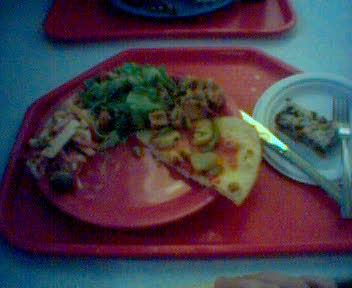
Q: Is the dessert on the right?
A: Yes, the dessert is on the right of the image.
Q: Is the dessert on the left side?
A: No, the dessert is on the right of the image.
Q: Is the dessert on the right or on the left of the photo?
A: The dessert is on the right of the image.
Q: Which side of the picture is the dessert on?
A: The dessert is on the right of the image.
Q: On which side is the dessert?
A: The dessert is on the right of the image.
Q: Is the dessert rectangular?
A: Yes, the dessert is rectangular.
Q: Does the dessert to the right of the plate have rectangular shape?
A: Yes, the dessert is rectangular.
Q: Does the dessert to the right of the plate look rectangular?
A: Yes, the dessert is rectangular.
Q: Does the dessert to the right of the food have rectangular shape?
A: Yes, the dessert is rectangular.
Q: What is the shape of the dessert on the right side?
A: The dessert is rectangular.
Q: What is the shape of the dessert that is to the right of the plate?
A: The dessert is rectangular.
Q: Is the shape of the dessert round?
A: No, the dessert is rectangular.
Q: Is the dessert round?
A: No, the dessert is rectangular.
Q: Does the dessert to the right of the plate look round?
A: No, the dessert is rectangular.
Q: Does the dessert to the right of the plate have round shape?
A: No, the dessert is rectangular.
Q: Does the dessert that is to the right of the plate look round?
A: No, the dessert is rectangular.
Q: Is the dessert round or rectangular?
A: The dessert is rectangular.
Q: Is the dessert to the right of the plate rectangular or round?
A: The dessert is rectangular.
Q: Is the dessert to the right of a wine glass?
A: No, the dessert is to the right of the plate.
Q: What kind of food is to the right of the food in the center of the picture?
A: The food is a dessert.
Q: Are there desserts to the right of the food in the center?
A: Yes, there is a dessert to the right of the food.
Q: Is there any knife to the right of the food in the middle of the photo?
A: No, there is a dessert to the right of the food.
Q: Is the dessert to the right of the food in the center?
A: Yes, the dessert is to the right of the food.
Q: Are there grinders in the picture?
A: No, there are no grinders.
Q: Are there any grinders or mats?
A: No, there are no grinders or mats.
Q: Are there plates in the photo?
A: Yes, there is a plate.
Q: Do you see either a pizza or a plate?
A: Yes, there is a plate.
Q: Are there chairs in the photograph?
A: No, there are no chairs.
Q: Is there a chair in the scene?
A: No, there are no chairs.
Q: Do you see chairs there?
A: No, there are no chairs.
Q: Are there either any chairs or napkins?
A: No, there are no chairs or napkins.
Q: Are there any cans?
A: No, there are no cans.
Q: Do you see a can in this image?
A: No, there are no cans.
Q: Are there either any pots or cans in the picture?
A: No, there are no cans or pots.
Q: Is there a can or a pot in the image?
A: No, there are no cans or pots.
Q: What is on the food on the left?
A: The decoration is on the food.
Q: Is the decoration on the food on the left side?
A: Yes, the decoration is on the food.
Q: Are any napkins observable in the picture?
A: No, there are no napkins.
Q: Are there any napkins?
A: No, there are no napkins.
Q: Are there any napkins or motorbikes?
A: No, there are no napkins or motorbikes.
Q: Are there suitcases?
A: No, there are no suitcases.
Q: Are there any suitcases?
A: No, there are no suitcases.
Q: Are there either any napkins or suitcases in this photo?
A: No, there are no suitcases or napkins.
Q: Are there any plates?
A: Yes, there is a plate.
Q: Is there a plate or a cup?
A: Yes, there is a plate.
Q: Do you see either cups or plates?
A: Yes, there is a plate.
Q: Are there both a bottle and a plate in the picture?
A: No, there is a plate but no bottles.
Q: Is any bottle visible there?
A: No, there are no bottles.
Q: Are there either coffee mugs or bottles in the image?
A: No, there are no bottles or coffee mugs.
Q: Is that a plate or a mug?
A: That is a plate.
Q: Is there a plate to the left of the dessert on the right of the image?
A: Yes, there is a plate to the left of the dessert.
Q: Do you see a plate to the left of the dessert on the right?
A: Yes, there is a plate to the left of the dessert.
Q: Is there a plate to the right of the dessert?
A: No, the plate is to the left of the dessert.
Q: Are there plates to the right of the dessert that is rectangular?
A: No, the plate is to the left of the dessert.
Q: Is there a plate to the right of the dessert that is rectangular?
A: No, the plate is to the left of the dessert.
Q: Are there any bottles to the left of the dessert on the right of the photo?
A: No, there is a plate to the left of the dessert.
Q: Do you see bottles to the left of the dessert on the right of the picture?
A: No, there is a plate to the left of the dessert.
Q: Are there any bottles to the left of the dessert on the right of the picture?
A: No, there is a plate to the left of the dessert.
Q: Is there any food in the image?
A: Yes, there is food.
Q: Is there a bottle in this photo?
A: No, there are no bottles.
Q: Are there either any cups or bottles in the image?
A: No, there are no bottles or cups.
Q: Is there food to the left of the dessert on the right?
A: Yes, there is food to the left of the dessert.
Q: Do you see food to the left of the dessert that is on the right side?
A: Yes, there is food to the left of the dessert.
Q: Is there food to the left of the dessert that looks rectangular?
A: Yes, there is food to the left of the dessert.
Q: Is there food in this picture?
A: Yes, there is food.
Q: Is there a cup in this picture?
A: No, there are no cups.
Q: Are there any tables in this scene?
A: Yes, there is a table.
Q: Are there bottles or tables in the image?
A: Yes, there is a table.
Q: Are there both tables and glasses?
A: No, there is a table but no glasses.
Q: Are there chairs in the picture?
A: No, there are no chairs.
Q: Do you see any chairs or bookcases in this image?
A: No, there are no chairs or bookcases.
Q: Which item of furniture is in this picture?
A: The piece of furniture is a table.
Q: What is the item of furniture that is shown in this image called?
A: The piece of furniture is a table.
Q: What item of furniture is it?
A: The piece of furniture is a table.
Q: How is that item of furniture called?
A: This is a table.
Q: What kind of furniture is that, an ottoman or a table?
A: This is a table.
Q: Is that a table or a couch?
A: That is a table.